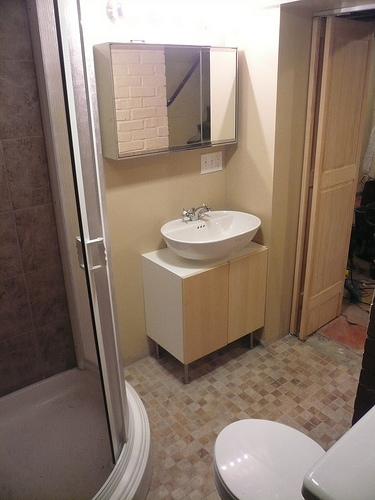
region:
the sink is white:
[153, 182, 267, 264]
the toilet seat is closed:
[192, 407, 277, 488]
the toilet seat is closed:
[183, 383, 329, 498]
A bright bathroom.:
[2, 1, 369, 496]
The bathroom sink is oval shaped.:
[156, 205, 258, 258]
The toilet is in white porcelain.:
[204, 413, 369, 492]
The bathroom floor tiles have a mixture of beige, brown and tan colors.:
[231, 351, 345, 411]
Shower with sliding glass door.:
[3, 3, 133, 494]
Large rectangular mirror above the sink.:
[97, 37, 240, 157]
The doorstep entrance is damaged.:
[307, 304, 369, 356]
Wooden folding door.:
[286, 11, 370, 341]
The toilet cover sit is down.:
[208, 414, 324, 494]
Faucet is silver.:
[180, 202, 211, 221]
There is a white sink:
[147, 193, 274, 277]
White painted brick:
[114, 51, 176, 139]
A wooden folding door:
[288, 10, 368, 353]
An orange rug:
[303, 297, 374, 362]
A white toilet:
[198, 389, 368, 498]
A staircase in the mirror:
[168, 52, 218, 148]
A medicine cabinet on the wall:
[91, 28, 247, 181]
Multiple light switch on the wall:
[189, 149, 239, 179]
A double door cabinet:
[170, 244, 276, 390]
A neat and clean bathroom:
[6, 4, 368, 494]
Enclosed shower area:
[0, 5, 157, 494]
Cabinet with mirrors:
[98, 30, 249, 161]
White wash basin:
[155, 201, 264, 253]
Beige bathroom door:
[291, 15, 368, 345]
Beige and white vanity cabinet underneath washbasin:
[142, 249, 275, 366]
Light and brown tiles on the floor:
[147, 376, 213, 466]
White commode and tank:
[212, 387, 372, 497]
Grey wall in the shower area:
[0, 2, 93, 403]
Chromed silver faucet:
[175, 198, 215, 224]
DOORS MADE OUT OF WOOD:
[203, 298, 216, 322]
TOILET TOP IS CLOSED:
[254, 436, 278, 479]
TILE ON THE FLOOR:
[172, 400, 185, 437]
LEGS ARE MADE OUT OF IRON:
[182, 367, 186, 383]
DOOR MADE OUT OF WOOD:
[319, 195, 336, 244]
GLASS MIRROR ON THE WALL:
[178, 71, 191, 111]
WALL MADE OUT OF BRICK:
[124, 70, 135, 117]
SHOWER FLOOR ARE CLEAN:
[57, 440, 76, 474]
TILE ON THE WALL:
[10, 176, 20, 218]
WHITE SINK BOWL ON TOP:
[180, 214, 259, 251]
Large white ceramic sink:
[154, 203, 264, 258]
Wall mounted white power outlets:
[195, 150, 228, 175]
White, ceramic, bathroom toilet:
[208, 400, 374, 495]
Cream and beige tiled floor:
[113, 329, 370, 498]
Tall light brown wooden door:
[286, 11, 373, 344]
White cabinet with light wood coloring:
[137, 240, 274, 387]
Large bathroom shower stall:
[1, 0, 166, 499]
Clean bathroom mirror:
[162, 40, 214, 161]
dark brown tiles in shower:
[0, 0, 155, 499]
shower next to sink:
[0, 0, 262, 498]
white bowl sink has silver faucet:
[159, 201, 261, 262]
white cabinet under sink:
[138, 205, 266, 384]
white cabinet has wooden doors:
[138, 240, 268, 384]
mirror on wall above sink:
[79, 0, 240, 365]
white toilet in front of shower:
[2, 0, 373, 498]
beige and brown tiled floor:
[121, 333, 361, 499]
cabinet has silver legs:
[140, 238, 268, 385]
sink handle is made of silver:
[179, 198, 211, 222]